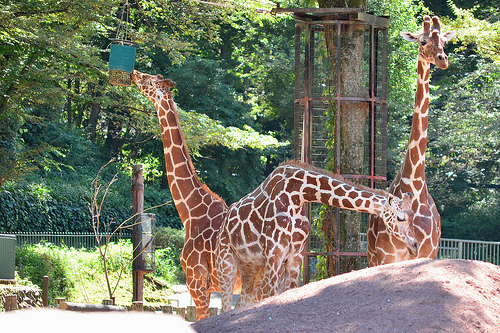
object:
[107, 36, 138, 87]
feeder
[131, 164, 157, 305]
post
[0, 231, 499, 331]
fence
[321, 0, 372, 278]
trunk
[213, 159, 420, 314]
giraffe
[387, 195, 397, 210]
ear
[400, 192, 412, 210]
horn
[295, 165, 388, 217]
neck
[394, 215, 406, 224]
eye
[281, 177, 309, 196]
spots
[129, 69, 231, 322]
giraffe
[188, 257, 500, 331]
rock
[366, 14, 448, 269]
giraffe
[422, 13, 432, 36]
horns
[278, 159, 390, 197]
mane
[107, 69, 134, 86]
food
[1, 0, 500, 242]
trees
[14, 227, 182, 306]
bushes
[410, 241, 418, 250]
nose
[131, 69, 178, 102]
head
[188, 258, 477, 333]
shadow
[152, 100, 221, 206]
neck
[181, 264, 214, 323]
legs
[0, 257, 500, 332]
ground